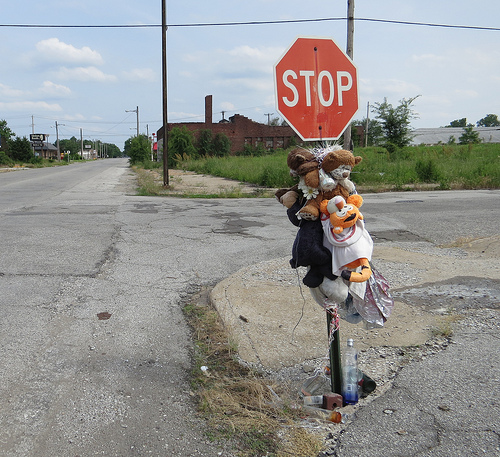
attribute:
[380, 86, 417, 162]
tree — green 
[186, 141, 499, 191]
grass — Green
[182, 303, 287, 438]
grass — Dying 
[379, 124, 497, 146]
building — rectangular, white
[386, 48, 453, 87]
sky — blue 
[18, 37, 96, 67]
cloud — white 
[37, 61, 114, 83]
cloud — white 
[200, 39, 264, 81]
cloud — white 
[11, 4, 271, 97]
sky — blue 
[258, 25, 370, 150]
sign — red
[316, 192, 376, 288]
tiger — dressed up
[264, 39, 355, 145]
stop sign — white and red  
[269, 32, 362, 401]
stop sign — red and white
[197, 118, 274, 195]
grass — small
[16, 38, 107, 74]
cloud — white 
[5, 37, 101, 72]
cloud — white 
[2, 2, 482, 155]
sky — cloudy, blue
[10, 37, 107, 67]
cloud — white 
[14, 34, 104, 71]
cloud — white 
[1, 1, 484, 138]
sky — blue 